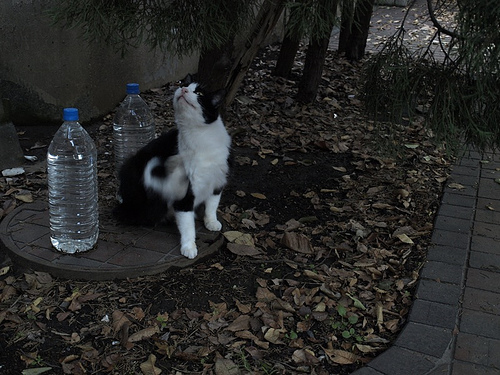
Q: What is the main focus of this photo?
A: A cat.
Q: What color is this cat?
A: Black and white.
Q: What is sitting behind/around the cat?
A: Water bottles.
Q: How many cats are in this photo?
A: One.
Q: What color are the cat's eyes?
A: Yellow.